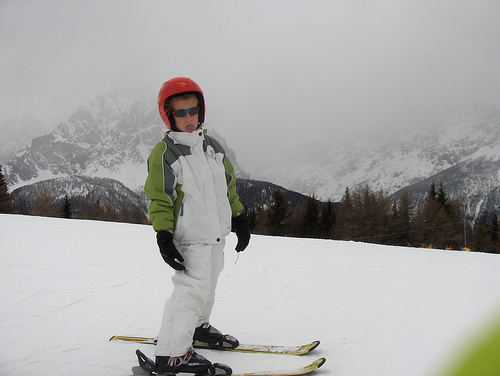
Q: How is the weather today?
A: It is foggy.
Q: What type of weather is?
A: It is foggy.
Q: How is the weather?
A: It is foggy.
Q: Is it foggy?
A: Yes, it is foggy.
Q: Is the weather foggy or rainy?
A: It is foggy.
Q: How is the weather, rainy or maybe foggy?
A: It is foggy.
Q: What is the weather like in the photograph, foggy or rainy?
A: It is foggy.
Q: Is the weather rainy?
A: No, it is foggy.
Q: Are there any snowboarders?
A: No, there are no snowboarders.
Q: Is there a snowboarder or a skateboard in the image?
A: No, there are no snowboarders or skateboards.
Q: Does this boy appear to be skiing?
A: Yes, the boy is skiing.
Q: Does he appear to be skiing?
A: Yes, the boy is skiing.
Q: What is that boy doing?
A: The boy is skiing.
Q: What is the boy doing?
A: The boy is skiing.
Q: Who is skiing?
A: The boy is skiing.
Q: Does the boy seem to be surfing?
A: No, the boy is skiing.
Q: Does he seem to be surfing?
A: No, the boy is skiing.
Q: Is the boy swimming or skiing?
A: The boy is skiing.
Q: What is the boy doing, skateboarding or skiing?
A: The boy is skiing.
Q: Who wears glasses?
A: The boy wears glasses.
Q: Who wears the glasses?
A: The boy wears glasses.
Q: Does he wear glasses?
A: Yes, the boy wears glasses.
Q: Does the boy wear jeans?
A: No, the boy wears glasses.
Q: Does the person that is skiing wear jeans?
A: No, the boy wears glasses.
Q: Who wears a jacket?
A: The boy wears a jacket.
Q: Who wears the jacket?
A: The boy wears a jacket.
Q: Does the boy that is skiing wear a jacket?
A: Yes, the boy wears a jacket.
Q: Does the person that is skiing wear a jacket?
A: Yes, the boy wears a jacket.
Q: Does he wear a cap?
A: No, the boy wears a jacket.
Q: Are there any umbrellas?
A: No, there are no umbrellas.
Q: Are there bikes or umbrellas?
A: No, there are no umbrellas or bikes.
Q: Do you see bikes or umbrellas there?
A: No, there are no umbrellas or bikes.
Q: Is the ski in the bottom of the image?
A: Yes, the ski is in the bottom of the image.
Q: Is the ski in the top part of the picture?
A: No, the ski is in the bottom of the image.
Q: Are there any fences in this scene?
A: No, there are no fences.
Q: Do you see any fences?
A: No, there are no fences.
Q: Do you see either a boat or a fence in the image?
A: No, there are no fences or boats.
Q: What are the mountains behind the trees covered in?
A: The mountains are covered in snow.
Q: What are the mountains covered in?
A: The mountains are covered in snow.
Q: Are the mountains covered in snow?
A: Yes, the mountains are covered in snow.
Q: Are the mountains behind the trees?
A: Yes, the mountains are behind the trees.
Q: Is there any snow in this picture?
A: Yes, there is snow.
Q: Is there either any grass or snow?
A: Yes, there is snow.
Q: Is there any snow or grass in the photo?
A: Yes, there is snow.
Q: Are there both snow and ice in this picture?
A: No, there is snow but no ice.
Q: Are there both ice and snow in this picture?
A: No, there is snow but no ice.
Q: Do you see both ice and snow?
A: No, there is snow but no ice.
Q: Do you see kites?
A: No, there are no kites.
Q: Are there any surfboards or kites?
A: No, there are no kites or surfboards.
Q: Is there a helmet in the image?
A: Yes, there is a helmet.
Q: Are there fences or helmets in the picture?
A: Yes, there is a helmet.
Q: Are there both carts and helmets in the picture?
A: No, there is a helmet but no carts.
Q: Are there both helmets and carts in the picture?
A: No, there is a helmet but no carts.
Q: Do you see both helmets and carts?
A: No, there is a helmet but no carts.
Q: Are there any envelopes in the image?
A: No, there are no envelopes.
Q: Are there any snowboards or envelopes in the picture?
A: No, there are no envelopes or snowboards.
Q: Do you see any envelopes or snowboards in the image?
A: No, there are no envelopes or snowboards.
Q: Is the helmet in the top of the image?
A: Yes, the helmet is in the top of the image.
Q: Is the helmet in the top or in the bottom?
A: The helmet is in the top of the image.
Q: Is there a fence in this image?
A: No, there are no fences.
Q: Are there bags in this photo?
A: No, there are no bags.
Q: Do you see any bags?
A: No, there are no bags.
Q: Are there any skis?
A: Yes, there are skis.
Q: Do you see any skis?
A: Yes, there are skis.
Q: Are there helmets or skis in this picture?
A: Yes, there are skis.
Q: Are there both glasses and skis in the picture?
A: Yes, there are both skis and glasses.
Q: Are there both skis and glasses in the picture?
A: Yes, there are both skis and glasses.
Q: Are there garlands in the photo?
A: No, there are no garlands.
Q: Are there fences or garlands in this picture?
A: No, there are no garlands or fences.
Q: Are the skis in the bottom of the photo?
A: Yes, the skis are in the bottom of the image.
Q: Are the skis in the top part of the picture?
A: No, the skis are in the bottom of the image.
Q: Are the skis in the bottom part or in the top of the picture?
A: The skis are in the bottom of the image.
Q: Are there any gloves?
A: Yes, there are gloves.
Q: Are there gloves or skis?
A: Yes, there are gloves.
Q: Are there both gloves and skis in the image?
A: Yes, there are both gloves and a ski.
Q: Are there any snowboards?
A: No, there are no snowboards.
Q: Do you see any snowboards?
A: No, there are no snowboards.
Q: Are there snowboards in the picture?
A: No, there are no snowboards.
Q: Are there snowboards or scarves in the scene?
A: No, there are no snowboards or scarves.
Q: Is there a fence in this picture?
A: No, there are no fences.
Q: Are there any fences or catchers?
A: No, there are no fences or catchers.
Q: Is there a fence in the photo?
A: No, there are no fences.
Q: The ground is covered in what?
A: The ground is covered in snow.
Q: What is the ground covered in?
A: The ground is covered in snow.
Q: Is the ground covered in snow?
A: Yes, the ground is covered in snow.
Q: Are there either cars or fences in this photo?
A: No, there are no cars or fences.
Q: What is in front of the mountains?
A: The trees are in front of the mountains.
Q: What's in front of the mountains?
A: The trees are in front of the mountains.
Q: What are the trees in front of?
A: The trees are in front of the mountains.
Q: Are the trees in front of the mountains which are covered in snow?
A: Yes, the trees are in front of the mountains.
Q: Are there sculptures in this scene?
A: No, there are no sculptures.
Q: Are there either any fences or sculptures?
A: No, there are no sculptures or fences.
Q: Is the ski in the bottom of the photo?
A: Yes, the ski is in the bottom of the image.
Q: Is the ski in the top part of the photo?
A: No, the ski is in the bottom of the image.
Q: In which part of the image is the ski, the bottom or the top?
A: The ski is in the bottom of the image.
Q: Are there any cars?
A: No, there are no cars.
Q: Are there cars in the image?
A: No, there are no cars.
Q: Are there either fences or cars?
A: No, there are no cars or fences.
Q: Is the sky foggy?
A: Yes, the sky is foggy.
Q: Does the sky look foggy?
A: Yes, the sky is foggy.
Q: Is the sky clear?
A: No, the sky is foggy.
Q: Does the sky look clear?
A: No, the sky is foggy.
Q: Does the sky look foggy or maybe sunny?
A: The sky is foggy.